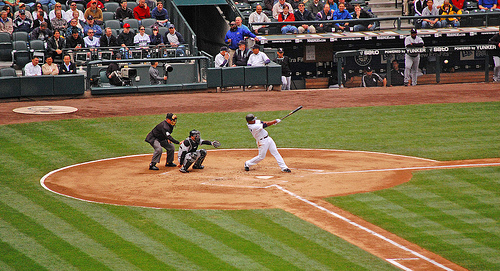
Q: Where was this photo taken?
A: At a baseball game.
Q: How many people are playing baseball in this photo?
A: Three.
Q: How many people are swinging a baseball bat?
A: One.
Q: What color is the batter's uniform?
A: White.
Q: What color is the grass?
A: Green.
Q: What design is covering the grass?
A: Stripes.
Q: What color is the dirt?
A: Brown.